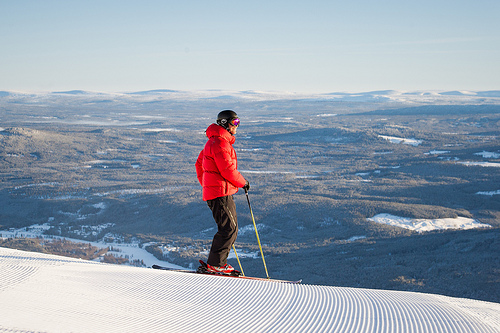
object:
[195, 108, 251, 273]
man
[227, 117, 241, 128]
goggles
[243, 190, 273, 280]
pole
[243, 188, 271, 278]
metal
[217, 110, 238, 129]
helmet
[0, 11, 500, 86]
sky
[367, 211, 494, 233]
patch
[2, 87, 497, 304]
landscape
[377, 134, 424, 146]
snow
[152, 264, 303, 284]
skis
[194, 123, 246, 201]
jacket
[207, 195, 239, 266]
pants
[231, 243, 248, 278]
rod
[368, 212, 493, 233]
snowy hill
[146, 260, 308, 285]
tracks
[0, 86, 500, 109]
mountains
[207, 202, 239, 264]
leg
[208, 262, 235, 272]
feet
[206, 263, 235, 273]
shoes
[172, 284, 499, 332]
lines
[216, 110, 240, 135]
head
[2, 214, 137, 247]
river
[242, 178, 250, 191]
gloves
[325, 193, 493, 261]
land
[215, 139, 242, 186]
arm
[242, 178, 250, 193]
hand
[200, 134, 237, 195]
body